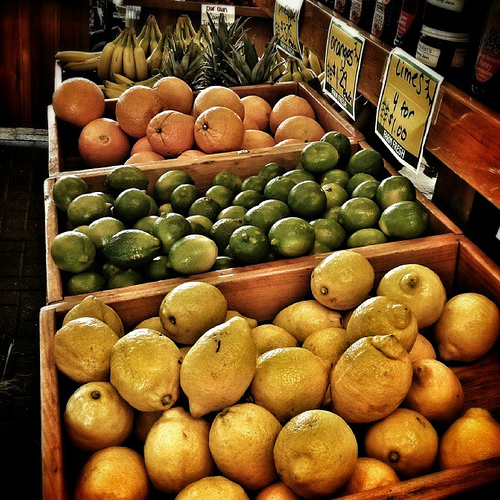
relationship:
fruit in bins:
[66, 17, 499, 497] [38, 1, 499, 497]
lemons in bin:
[58, 255, 497, 500] [34, 233, 499, 500]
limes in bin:
[52, 139, 424, 288] [15, 125, 449, 276]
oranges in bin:
[67, 92, 324, 164] [35, 79, 362, 177]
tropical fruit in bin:
[58, 41, 320, 84] [41, 34, 330, 114]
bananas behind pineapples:
[265, 38, 326, 90] [162, 11, 289, 87]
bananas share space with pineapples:
[52, 10, 329, 104] [162, 11, 289, 87]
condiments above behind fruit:
[315, 1, 499, 113] [66, 17, 499, 497]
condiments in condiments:
[415, 20, 473, 85] [415, 20, 473, 85]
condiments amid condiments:
[415, 20, 473, 85] [315, 1, 499, 113]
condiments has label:
[415, 20, 473, 85] [411, 39, 443, 66]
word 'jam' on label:
[422, 51, 431, 63] [411, 39, 443, 66]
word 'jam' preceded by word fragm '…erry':
[422, 51, 431, 63] [415, 50, 423, 56]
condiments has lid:
[415, 20, 473, 85] [418, 19, 472, 42]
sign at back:
[202, 3, 236, 31] [1, 0, 274, 130]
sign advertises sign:
[202, 3, 236, 31] [202, 3, 236, 31]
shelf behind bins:
[259, 3, 499, 218] [38, 1, 499, 497]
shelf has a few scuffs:
[259, 3, 499, 218] [428, 107, 499, 205]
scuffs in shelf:
[428, 107, 499, 205] [259, 3, 499, 218]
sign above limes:
[369, 43, 445, 173] [52, 139, 424, 288]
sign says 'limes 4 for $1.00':
[369, 43, 445, 173] [379, 61, 421, 148]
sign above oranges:
[318, 30, 367, 106] [67, 92, 324, 164]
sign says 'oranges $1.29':
[318, 30, 367, 106] [329, 34, 352, 88]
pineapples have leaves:
[162, 11, 289, 87] [202, 9, 274, 85]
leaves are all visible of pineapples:
[202, 9, 274, 85] [162, 11, 289, 87]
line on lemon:
[209, 336, 229, 355] [177, 310, 262, 419]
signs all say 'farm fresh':
[272, 0, 443, 171] [272, 38, 418, 174]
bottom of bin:
[388, 317, 499, 441] [34, 233, 499, 500]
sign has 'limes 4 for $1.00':
[369, 43, 445, 173] [379, 58, 424, 144]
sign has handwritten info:
[318, 30, 367, 106] [324, 28, 365, 106]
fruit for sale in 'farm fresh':
[66, 17, 499, 497] [0, 4, 499, 499]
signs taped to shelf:
[272, 0, 443, 171] [259, 3, 499, 218]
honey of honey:
[473, 38, 500, 110] [474, 56, 494, 70]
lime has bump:
[153, 209, 195, 246] [157, 209, 170, 219]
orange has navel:
[74, 111, 135, 169] [95, 131, 116, 145]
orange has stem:
[142, 109, 198, 156] [151, 123, 168, 135]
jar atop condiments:
[420, 1, 476, 33] [415, 20, 473, 85]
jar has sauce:
[369, 0, 398, 41] [371, 17, 385, 29]